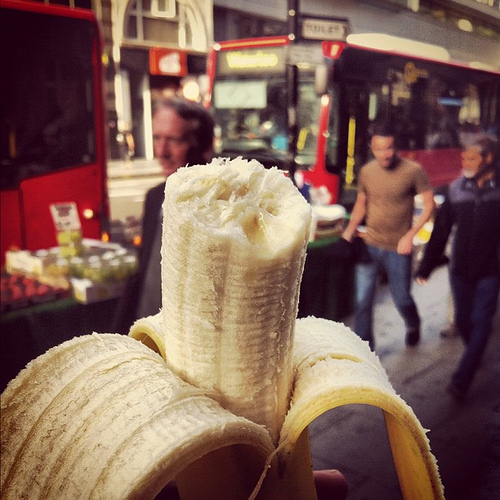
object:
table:
[4, 200, 364, 380]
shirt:
[415, 173, 498, 284]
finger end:
[313, 467, 348, 496]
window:
[434, 84, 486, 130]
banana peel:
[0, 313, 447, 500]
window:
[388, 84, 419, 122]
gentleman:
[335, 121, 437, 353]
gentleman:
[411, 137, 498, 403]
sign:
[296, 17, 349, 41]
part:
[164, 155, 311, 259]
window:
[366, 91, 380, 126]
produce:
[17, 235, 130, 296]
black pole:
[283, 0, 299, 176]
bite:
[158, 152, 314, 261]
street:
[2, 211, 498, 496]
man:
[108, 95, 217, 346]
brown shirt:
[356, 158, 431, 250]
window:
[211, 45, 326, 161]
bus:
[1, 0, 113, 253]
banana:
[0, 154, 442, 499]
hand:
[396, 231, 414, 255]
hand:
[337, 231, 354, 260]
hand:
[413, 260, 438, 285]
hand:
[310, 466, 351, 499]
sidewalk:
[289, 259, 500, 496]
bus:
[201, 34, 500, 207]